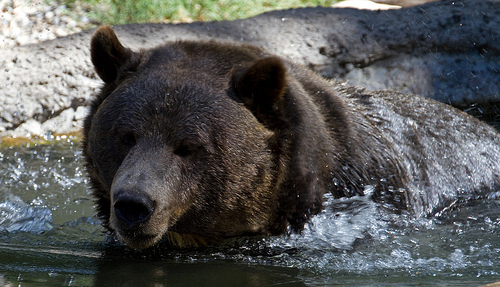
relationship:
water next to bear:
[316, 215, 358, 246] [84, 20, 488, 252]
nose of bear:
[104, 185, 158, 220] [84, 20, 488, 252]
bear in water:
[84, 20, 488, 252] [316, 215, 358, 246]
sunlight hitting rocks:
[24, 52, 55, 97] [21, 84, 60, 113]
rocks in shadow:
[403, 23, 438, 52] [450, 12, 487, 91]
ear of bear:
[225, 40, 285, 128] [84, 20, 488, 252]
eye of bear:
[169, 140, 194, 155] [84, 20, 488, 252]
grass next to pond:
[105, 2, 140, 16] [325, 201, 374, 239]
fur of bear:
[134, 68, 173, 98] [84, 20, 488, 252]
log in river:
[285, 8, 497, 58] [325, 201, 374, 239]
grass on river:
[105, 2, 140, 16] [312, 202, 363, 243]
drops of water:
[443, 238, 470, 258] [316, 215, 358, 246]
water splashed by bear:
[316, 215, 358, 246] [84, 20, 488, 252]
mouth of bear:
[110, 222, 158, 247] [84, 20, 488, 252]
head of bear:
[83, 27, 282, 248] [84, 20, 488, 252]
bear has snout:
[84, 20, 488, 252] [118, 153, 167, 243]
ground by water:
[47, 6, 82, 32] [316, 215, 358, 246]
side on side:
[15, 15, 60, 39] [15, 15, 55, 46]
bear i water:
[84, 20, 488, 252] [316, 215, 358, 246]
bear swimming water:
[84, 20, 488, 252] [316, 215, 358, 246]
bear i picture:
[84, 20, 488, 252] [14, 1, 480, 281]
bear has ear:
[84, 20, 488, 252] [225, 40, 285, 128]